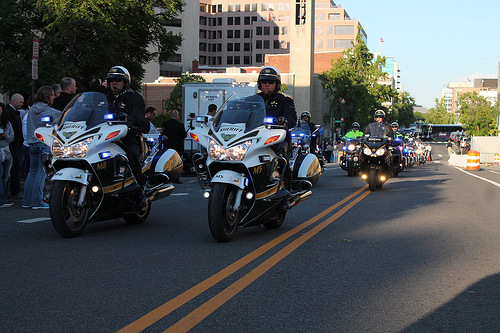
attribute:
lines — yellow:
[144, 260, 316, 313]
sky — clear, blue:
[335, 3, 497, 78]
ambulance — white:
[180, 74, 258, 172]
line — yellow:
[157, 183, 375, 331]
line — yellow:
[116, 176, 371, 329]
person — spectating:
[3, 93, 25, 196]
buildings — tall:
[141, 0, 498, 116]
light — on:
[246, 188, 256, 200]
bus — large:
[412, 120, 463, 142]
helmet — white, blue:
[255, 65, 283, 82]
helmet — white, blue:
[104, 60, 130, 76]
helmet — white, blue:
[367, 107, 387, 119]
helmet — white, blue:
[298, 110, 315, 120]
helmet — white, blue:
[389, 117, 400, 126]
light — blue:
[99, 150, 112, 159]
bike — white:
[181, 105, 333, 253]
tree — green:
[5, 1, 182, 103]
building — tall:
[366, 53, 425, 113]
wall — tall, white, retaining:
[470, 137, 499, 163]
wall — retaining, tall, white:
[311, 1, 361, 79]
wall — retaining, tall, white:
[454, 85, 498, 104]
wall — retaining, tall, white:
[195, 2, 290, 77]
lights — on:
[203, 128, 275, 173]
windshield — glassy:
[55, 90, 110, 130]